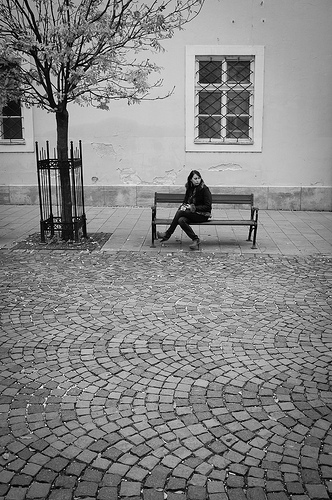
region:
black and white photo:
[11, 16, 315, 289]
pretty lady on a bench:
[145, 169, 292, 255]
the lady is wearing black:
[161, 170, 216, 260]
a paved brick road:
[21, 264, 304, 438]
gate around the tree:
[19, 130, 107, 246]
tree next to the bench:
[8, 33, 227, 263]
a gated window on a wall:
[172, 36, 285, 156]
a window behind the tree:
[2, 13, 55, 168]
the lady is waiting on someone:
[151, 168, 231, 269]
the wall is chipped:
[79, 134, 271, 197]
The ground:
[174, 369, 321, 498]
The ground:
[216, 415, 247, 474]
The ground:
[202, 402, 239, 447]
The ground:
[233, 401, 234, 493]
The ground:
[205, 438, 223, 477]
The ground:
[225, 459, 232, 486]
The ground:
[220, 395, 234, 436]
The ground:
[225, 432, 233, 478]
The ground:
[205, 441, 241, 498]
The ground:
[195, 416, 220, 489]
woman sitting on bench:
[154, 167, 213, 252]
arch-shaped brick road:
[17, 263, 315, 474]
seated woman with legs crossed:
[158, 168, 216, 254]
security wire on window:
[192, 53, 253, 146]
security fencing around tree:
[29, 135, 88, 245]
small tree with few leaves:
[1, 0, 208, 247]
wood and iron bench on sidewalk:
[146, 186, 261, 251]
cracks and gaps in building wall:
[88, 134, 183, 189]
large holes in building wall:
[228, 14, 274, 25]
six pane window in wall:
[182, 39, 265, 151]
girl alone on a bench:
[144, 163, 270, 255]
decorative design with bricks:
[56, 310, 275, 404]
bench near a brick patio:
[146, 184, 275, 241]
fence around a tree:
[32, 141, 101, 247]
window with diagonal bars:
[186, 46, 270, 160]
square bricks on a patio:
[101, 399, 245, 480]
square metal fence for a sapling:
[26, 135, 103, 244]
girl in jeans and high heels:
[159, 165, 216, 258]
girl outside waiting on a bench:
[138, 162, 294, 267]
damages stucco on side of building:
[90, 134, 145, 189]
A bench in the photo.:
[222, 190, 260, 235]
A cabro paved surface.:
[157, 314, 241, 368]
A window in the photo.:
[197, 57, 251, 138]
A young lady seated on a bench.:
[156, 169, 211, 253]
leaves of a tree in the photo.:
[58, 27, 123, 78]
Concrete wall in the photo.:
[280, 34, 317, 145]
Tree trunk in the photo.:
[52, 118, 70, 161]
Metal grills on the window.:
[9, 119, 24, 137]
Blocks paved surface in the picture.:
[277, 227, 304, 248]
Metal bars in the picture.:
[35, 181, 53, 238]